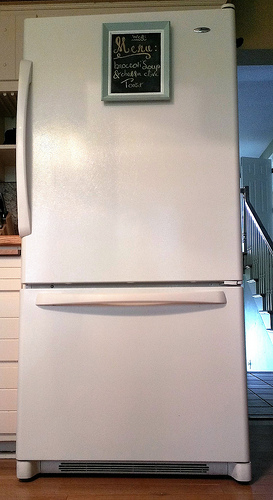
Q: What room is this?
A: It is a kitchen.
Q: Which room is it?
A: It is a kitchen.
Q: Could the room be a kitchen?
A: Yes, it is a kitchen.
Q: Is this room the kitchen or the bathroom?
A: It is the kitchen.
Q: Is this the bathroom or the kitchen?
A: It is the kitchen.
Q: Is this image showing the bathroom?
A: No, the picture is showing the kitchen.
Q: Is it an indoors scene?
A: Yes, it is indoors.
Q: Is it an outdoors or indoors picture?
A: It is indoors.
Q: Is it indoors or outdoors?
A: It is indoors.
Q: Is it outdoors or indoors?
A: It is indoors.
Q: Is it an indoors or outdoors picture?
A: It is indoors.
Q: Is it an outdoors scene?
A: No, it is indoors.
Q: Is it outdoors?
A: No, it is indoors.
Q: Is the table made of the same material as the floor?
A: Yes, both the table and the floor are made of wood.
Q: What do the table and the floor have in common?
A: The material, both the table and the floor are wooden.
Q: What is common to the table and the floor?
A: The material, both the table and the floor are wooden.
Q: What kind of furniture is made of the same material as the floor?
A: The table is made of the same material as the floor.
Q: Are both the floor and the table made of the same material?
A: Yes, both the floor and the table are made of wood.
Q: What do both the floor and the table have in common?
A: The material, both the floor and the table are wooden.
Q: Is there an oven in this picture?
A: No, there are no ovens.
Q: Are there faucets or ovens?
A: No, there are no ovens or faucets.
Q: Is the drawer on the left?
A: Yes, the drawer is on the left of the image.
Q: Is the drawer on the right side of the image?
A: No, the drawer is on the left of the image.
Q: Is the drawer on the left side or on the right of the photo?
A: The drawer is on the left of the image.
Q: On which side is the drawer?
A: The drawer is on the left of the image.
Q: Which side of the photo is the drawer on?
A: The drawer is on the left of the image.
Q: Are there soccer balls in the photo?
A: No, there are no soccer balls.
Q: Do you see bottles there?
A: No, there are no bottles.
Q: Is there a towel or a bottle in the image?
A: No, there are no bottles or towels.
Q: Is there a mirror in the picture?
A: No, there are no mirrors.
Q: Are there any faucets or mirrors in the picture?
A: No, there are no mirrors or faucets.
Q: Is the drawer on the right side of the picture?
A: No, the drawer is on the left of the image.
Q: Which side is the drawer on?
A: The drawer is on the left of the image.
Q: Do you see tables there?
A: Yes, there is a table.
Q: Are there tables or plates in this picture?
A: Yes, there is a table.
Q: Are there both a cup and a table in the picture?
A: No, there is a table but no cups.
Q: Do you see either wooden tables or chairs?
A: Yes, there is a wood table.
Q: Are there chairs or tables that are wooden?
A: Yes, the table is wooden.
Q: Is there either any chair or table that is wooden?
A: Yes, the table is wooden.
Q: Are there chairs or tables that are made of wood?
A: Yes, the table is made of wood.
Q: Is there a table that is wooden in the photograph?
A: Yes, there is a wood table.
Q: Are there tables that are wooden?
A: Yes, there is a table that is wooden.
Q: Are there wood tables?
A: Yes, there is a table that is made of wood.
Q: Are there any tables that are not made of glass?
A: Yes, there is a table that is made of wood.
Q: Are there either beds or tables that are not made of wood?
A: No, there is a table but it is made of wood.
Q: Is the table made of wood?
A: Yes, the table is made of wood.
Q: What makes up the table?
A: The table is made of wood.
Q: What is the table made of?
A: The table is made of wood.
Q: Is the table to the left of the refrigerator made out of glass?
A: No, the table is made of wood.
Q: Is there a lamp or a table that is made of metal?
A: No, there is a table but it is made of wood.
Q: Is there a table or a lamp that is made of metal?
A: No, there is a table but it is made of wood.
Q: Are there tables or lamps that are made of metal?
A: No, there is a table but it is made of wood.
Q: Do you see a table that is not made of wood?
A: No, there is a table but it is made of wood.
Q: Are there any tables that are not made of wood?
A: No, there is a table but it is made of wood.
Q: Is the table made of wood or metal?
A: The table is made of wood.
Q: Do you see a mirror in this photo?
A: No, there are no mirrors.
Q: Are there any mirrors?
A: No, there are no mirrors.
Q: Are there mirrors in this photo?
A: No, there are no mirrors.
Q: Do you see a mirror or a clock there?
A: No, there are no mirrors or clocks.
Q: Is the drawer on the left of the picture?
A: Yes, the drawer is on the left of the image.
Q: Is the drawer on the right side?
A: No, the drawer is on the left of the image.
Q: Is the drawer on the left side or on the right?
A: The drawer is on the left of the image.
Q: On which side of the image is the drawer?
A: The drawer is on the left of the image.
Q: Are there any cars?
A: No, there are no cars.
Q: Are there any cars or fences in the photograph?
A: No, there are no cars or fences.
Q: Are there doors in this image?
A: Yes, there is a door.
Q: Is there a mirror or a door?
A: Yes, there is a door.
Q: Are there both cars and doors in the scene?
A: No, there is a door but no cars.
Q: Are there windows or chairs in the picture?
A: No, there are no chairs or windows.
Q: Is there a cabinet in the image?
A: Yes, there is a cabinet.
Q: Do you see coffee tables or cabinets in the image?
A: Yes, there is a cabinet.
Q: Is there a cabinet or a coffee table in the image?
A: Yes, there is a cabinet.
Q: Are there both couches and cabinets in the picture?
A: No, there is a cabinet but no couches.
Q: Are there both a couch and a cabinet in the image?
A: No, there is a cabinet but no couches.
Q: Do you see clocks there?
A: No, there are no clocks.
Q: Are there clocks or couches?
A: No, there are no clocks or couches.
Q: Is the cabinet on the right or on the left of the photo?
A: The cabinet is on the left of the image.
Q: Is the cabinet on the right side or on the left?
A: The cabinet is on the left of the image.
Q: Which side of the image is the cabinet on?
A: The cabinet is on the left of the image.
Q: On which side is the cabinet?
A: The cabinet is on the left of the image.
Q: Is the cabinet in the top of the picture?
A: Yes, the cabinet is in the top of the image.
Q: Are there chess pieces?
A: No, there are no chess pieces.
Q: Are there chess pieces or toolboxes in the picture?
A: No, there are no chess pieces or toolboxes.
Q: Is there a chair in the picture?
A: No, there are no chairs.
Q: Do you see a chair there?
A: No, there are no chairs.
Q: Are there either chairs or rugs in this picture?
A: No, there are no chairs or rugs.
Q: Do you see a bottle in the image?
A: No, there are no bottles.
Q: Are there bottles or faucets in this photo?
A: No, there are no bottles or faucets.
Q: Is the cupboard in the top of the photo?
A: Yes, the cupboard is in the top of the image.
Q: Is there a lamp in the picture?
A: No, there are no lamps.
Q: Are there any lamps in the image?
A: No, there are no lamps.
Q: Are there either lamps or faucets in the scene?
A: No, there are no lamps or faucets.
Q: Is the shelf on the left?
A: Yes, the shelf is on the left of the image.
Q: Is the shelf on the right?
A: No, the shelf is on the left of the image.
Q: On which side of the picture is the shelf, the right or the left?
A: The shelf is on the left of the image.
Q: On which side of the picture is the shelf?
A: The shelf is on the left of the image.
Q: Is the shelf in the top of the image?
A: Yes, the shelf is in the top of the image.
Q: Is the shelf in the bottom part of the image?
A: No, the shelf is in the top of the image.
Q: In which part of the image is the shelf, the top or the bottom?
A: The shelf is in the top of the image.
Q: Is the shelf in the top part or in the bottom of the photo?
A: The shelf is in the top of the image.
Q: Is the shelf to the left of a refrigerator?
A: Yes, the shelf is to the left of a refrigerator.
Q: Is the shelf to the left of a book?
A: No, the shelf is to the left of a refrigerator.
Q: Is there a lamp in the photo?
A: No, there are no lamps.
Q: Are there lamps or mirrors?
A: No, there are no lamps or mirrors.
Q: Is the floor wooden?
A: Yes, the floor is wooden.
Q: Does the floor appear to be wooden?
A: Yes, the floor is wooden.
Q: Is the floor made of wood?
A: Yes, the floor is made of wood.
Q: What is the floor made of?
A: The floor is made of wood.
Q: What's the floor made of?
A: The floor is made of wood.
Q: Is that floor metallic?
A: No, the floor is wooden.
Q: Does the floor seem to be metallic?
A: No, the floor is wooden.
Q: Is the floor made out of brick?
A: No, the floor is made of wood.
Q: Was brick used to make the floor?
A: No, the floor is made of wood.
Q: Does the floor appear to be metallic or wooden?
A: The floor is wooden.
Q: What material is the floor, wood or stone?
A: The floor is made of wood.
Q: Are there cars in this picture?
A: No, there are no cars.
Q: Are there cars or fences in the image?
A: No, there are no cars or fences.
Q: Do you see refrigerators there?
A: Yes, there is a refrigerator.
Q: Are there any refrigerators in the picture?
A: Yes, there is a refrigerator.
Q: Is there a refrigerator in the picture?
A: Yes, there is a refrigerator.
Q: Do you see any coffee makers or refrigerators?
A: Yes, there is a refrigerator.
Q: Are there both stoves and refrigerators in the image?
A: No, there is a refrigerator but no stoves.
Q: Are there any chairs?
A: No, there are no chairs.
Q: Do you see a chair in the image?
A: No, there are no chairs.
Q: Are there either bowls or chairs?
A: No, there are no chairs or bowls.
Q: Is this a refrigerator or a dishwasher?
A: This is a refrigerator.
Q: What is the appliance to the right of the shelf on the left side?
A: The appliance is a refrigerator.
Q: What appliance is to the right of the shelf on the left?
A: The appliance is a refrigerator.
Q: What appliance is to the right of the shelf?
A: The appliance is a refrigerator.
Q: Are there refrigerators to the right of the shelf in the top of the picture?
A: Yes, there is a refrigerator to the right of the shelf.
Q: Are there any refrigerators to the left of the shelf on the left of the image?
A: No, the refrigerator is to the right of the shelf.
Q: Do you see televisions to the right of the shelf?
A: No, there is a refrigerator to the right of the shelf.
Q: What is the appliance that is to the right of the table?
A: The appliance is a refrigerator.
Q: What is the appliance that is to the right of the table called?
A: The appliance is a refrigerator.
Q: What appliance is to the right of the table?
A: The appliance is a refrigerator.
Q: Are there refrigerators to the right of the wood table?
A: Yes, there is a refrigerator to the right of the table.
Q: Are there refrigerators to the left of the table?
A: No, the refrigerator is to the right of the table.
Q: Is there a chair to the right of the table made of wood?
A: No, there is a refrigerator to the right of the table.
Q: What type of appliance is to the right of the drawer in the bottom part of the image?
A: The appliance is a refrigerator.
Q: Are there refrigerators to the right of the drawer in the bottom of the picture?
A: Yes, there is a refrigerator to the right of the drawer.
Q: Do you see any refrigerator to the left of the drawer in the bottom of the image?
A: No, the refrigerator is to the right of the drawer.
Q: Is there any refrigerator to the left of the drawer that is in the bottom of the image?
A: No, the refrigerator is to the right of the drawer.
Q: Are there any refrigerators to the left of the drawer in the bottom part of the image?
A: No, the refrigerator is to the right of the drawer.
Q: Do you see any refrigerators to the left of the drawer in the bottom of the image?
A: No, the refrigerator is to the right of the drawer.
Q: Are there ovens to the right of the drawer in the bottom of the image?
A: No, there is a refrigerator to the right of the drawer.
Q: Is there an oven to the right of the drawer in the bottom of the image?
A: No, there is a refrigerator to the right of the drawer.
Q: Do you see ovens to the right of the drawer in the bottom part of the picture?
A: No, there is a refrigerator to the right of the drawer.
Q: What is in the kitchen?
A: The refrigerator is in the kitchen.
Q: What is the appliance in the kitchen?
A: The appliance is a refrigerator.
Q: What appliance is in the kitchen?
A: The appliance is a refrigerator.